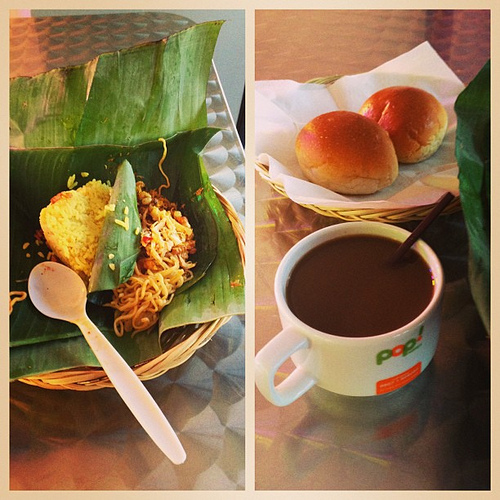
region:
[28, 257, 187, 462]
the white plastic spoon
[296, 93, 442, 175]
the two buns in the basket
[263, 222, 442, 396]
the pop! coffee mug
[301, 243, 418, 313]
the dark liquid in the coffee mug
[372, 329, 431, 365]
the orange and green letters on the coffee mug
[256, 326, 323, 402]
the handle of the coffee mug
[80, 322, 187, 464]
the handle of the spoon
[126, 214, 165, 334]
the noodles on the leaves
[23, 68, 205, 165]
the big leaves in the basket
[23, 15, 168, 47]
the silver table top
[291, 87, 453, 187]
Two small golden loaves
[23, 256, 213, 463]
Spoon with food particles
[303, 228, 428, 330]
Hot cocoa in mug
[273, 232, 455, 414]
White coffee mug with handle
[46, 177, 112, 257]
Piece of yellow cornbread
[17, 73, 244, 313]
Green wrapper underneath food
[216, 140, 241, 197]
Corrugated pattern on tablecloth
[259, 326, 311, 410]
Handle of coffee mug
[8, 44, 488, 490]
Two pictures of food side-by-side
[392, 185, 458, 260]
Straw in brown beverage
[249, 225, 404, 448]
A cup is visible.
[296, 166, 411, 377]
A cup is visible.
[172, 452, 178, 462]
edge of a spoon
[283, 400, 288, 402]
handle of a cup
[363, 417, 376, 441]
top of a table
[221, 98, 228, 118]
side of a tale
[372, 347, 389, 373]
side of a cup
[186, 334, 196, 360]
part of a sisal plate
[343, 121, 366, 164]
part of a scorn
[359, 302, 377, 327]
black drink on the cup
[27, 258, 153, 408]
white spoon in basket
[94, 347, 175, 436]
handle of the spoon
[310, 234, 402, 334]
brown liquid in cup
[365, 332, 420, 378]
green and orange writing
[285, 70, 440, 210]
two buns in bowl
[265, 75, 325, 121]
white paper under buns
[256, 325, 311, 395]
handle of the cup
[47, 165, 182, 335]
food in the basket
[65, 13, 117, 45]
silver table under basket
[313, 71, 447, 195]
two round buns in a basket